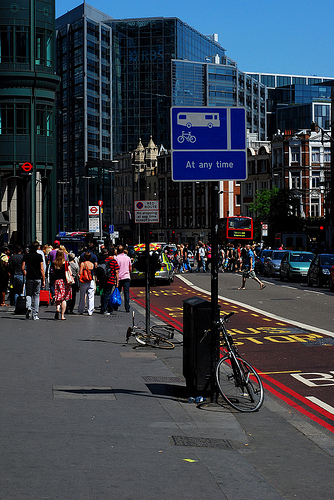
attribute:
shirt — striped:
[104, 256, 119, 283]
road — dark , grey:
[200, 238, 313, 402]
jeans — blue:
[23, 274, 41, 319]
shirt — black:
[21, 251, 46, 279]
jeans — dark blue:
[115, 275, 132, 312]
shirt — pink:
[107, 248, 134, 285]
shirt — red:
[101, 257, 121, 286]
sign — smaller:
[131, 197, 163, 232]